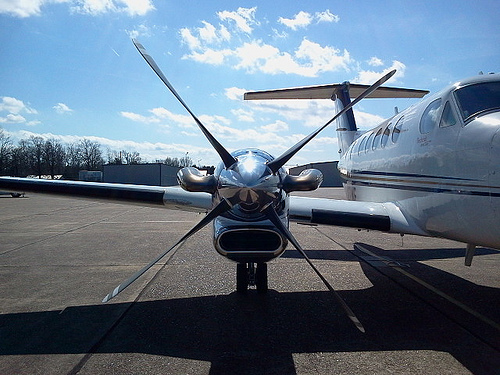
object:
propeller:
[101, 36, 397, 336]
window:
[392, 116, 403, 143]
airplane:
[6, 36, 498, 297]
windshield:
[441, 78, 499, 130]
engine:
[212, 220, 295, 268]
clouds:
[216, 11, 323, 60]